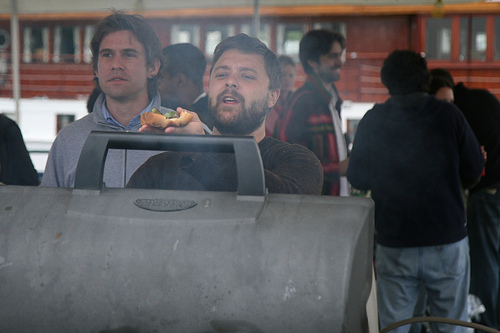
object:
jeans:
[374, 234, 476, 332]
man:
[343, 47, 488, 332]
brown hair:
[88, 5, 167, 87]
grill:
[0, 184, 378, 332]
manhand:
[337, 156, 352, 177]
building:
[1, 0, 499, 155]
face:
[205, 49, 270, 125]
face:
[93, 31, 150, 102]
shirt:
[345, 92, 488, 252]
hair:
[209, 31, 283, 91]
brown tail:
[73, 130, 269, 197]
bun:
[138, 108, 191, 129]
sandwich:
[137, 107, 194, 130]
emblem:
[131, 197, 197, 211]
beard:
[316, 64, 341, 82]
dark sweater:
[125, 137, 324, 197]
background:
[0, 0, 499, 332]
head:
[89, 12, 163, 100]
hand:
[137, 107, 207, 135]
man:
[123, 31, 328, 195]